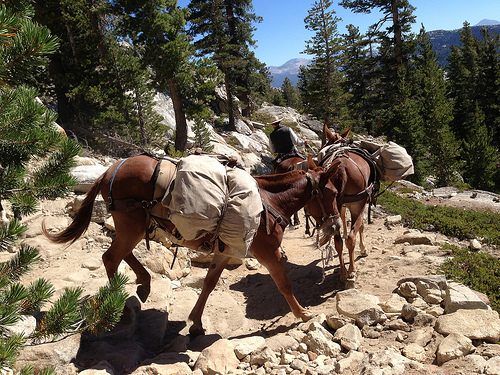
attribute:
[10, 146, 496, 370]
terrain — rocky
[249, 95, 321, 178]
man — long, sleeved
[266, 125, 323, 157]
shirt — white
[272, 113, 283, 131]
hat — cowboy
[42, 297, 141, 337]
needles — pine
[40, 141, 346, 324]
horse —  brown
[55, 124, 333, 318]
horse —  brown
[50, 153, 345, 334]
horse —  brown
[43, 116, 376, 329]
horse —  brown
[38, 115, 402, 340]
horse —  brown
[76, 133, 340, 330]
horse —  brown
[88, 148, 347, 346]
horse —  brown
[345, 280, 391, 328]
rocks — ground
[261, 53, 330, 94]
mountain range — blue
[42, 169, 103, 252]
tail — beautiful, bushy, brown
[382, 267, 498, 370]
rocks — piled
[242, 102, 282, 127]
hat — tan